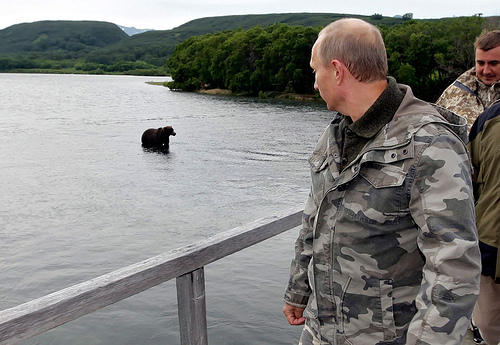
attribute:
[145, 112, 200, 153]
horse — large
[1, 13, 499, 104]
green trees — large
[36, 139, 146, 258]
water — clear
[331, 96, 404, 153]
shirt — green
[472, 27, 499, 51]
hair — brown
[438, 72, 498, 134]
coat — brown 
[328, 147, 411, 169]
buttons — silver 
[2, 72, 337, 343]
water — dark, murky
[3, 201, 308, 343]
hand rails — wooden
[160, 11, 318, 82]
hills — green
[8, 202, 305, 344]
railing — wooden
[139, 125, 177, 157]
bear — large 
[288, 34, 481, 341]
man — bald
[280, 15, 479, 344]
man — balding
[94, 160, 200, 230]
water — clear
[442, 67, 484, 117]
jacket — brown, camouflage